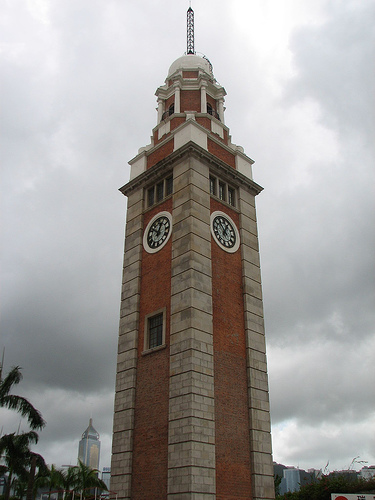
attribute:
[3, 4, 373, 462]
clouds — white, heavy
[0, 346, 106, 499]
tree branches — in the photo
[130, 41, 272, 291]
tower — stone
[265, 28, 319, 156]
cloudy skies — in the photo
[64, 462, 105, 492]
trees — in the photo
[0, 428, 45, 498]
trees — in the photo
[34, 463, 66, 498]
trees — in the photo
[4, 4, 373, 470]
cloudy sky — grey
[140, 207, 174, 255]
clock — white, black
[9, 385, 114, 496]
palm trees — small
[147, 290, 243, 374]
wall — stone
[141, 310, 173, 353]
window — stone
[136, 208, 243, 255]
clock — large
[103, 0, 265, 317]
tower — clock tower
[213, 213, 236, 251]
clock — white, black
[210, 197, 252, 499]
wall — brick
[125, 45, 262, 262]
building — tall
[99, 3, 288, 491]
tower — tan, blue, in the photo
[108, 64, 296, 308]
tower — large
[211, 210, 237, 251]
clock — black, white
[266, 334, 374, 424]
cloud — white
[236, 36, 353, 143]
clouds — white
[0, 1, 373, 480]
sky — blue